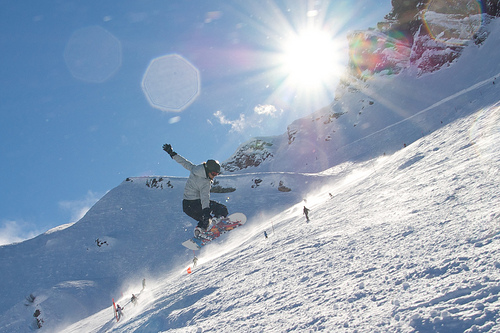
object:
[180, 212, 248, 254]
snowboard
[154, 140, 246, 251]
snow boarder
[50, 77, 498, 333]
ground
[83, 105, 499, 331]
snow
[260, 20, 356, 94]
sun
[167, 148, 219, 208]
jacket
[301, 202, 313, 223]
person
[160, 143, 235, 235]
snowboarder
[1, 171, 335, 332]
hill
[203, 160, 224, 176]
helmet